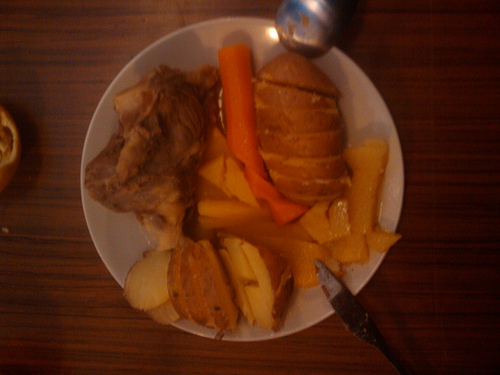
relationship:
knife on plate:
[310, 261, 415, 371] [84, 96, 396, 303]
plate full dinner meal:
[66, 0, 389, 338] [83, 44, 402, 332]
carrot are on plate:
[219, 47, 299, 225] [70, 11, 410, 348]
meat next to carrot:
[82, 61, 206, 211] [219, 47, 299, 225]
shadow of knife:
[370, 264, 437, 370] [312, 255, 412, 373]